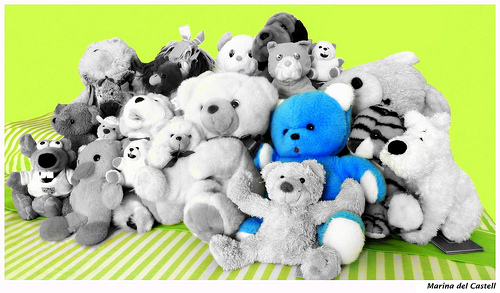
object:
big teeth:
[35, 169, 65, 187]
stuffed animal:
[4, 133, 77, 221]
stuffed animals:
[38, 138, 125, 246]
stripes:
[115, 241, 185, 281]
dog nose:
[386, 139, 407, 155]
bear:
[209, 158, 365, 280]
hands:
[334, 177, 366, 217]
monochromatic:
[101, 88, 248, 223]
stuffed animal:
[306, 41, 344, 83]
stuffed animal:
[37, 138, 123, 245]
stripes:
[364, 253, 493, 279]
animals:
[130, 70, 279, 244]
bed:
[5, 243, 113, 274]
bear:
[235, 90, 387, 264]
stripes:
[7, 246, 84, 282]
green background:
[0, 5, 498, 158]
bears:
[145, 115, 208, 170]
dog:
[378, 109, 483, 245]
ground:
[4, 246, 173, 277]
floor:
[3, 193, 499, 281]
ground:
[212, 250, 497, 280]